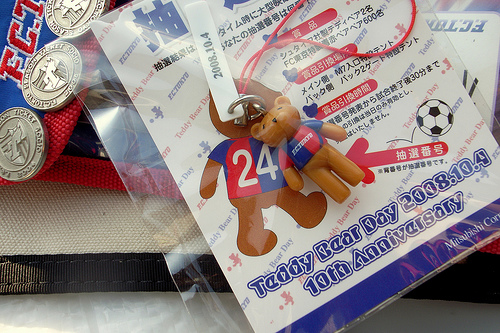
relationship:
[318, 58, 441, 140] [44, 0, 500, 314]
writing on card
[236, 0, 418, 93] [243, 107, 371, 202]
string attached to bear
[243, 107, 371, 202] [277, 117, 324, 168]
bear wearing a jersey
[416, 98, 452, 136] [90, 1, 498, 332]
soccer ball on card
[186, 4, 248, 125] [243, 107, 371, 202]
id tag attached to bear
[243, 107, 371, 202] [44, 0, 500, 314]
bear in a package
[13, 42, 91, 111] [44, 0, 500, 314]
coin next to package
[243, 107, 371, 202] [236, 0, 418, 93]
bear attached to string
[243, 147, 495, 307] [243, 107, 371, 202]
writing below bear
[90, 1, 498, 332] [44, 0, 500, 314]
card wrapped in a package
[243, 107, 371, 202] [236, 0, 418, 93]
bear attached to a string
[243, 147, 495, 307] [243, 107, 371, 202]
writing beneath bear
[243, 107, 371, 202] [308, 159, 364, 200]
bear has legs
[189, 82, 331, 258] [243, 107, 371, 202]
drawing behind bear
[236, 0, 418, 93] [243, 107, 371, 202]
string above bear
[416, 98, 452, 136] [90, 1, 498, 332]
soccer ball drawn on card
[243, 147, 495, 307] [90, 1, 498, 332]
writing on card